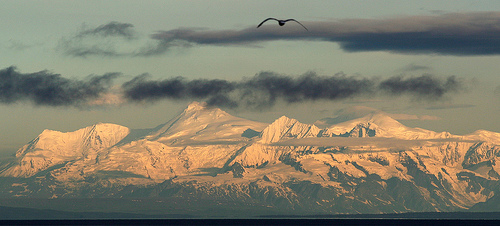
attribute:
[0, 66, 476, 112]
cloud — black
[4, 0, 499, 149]
sky — dark grey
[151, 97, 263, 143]
mountain — snow-covered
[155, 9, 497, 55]
cloud — grey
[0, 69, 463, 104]
cloud — grey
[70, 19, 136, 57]
cloud — grey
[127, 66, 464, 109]
grey cloud — dark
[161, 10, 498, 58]
grey cloud — dark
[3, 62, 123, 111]
grey cloud — dark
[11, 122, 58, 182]
mountains — rocky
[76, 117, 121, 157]
mountains — rocky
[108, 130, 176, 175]
mountains — rocky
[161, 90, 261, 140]
mountains — rocky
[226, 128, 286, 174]
mountains — rocky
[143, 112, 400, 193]
mountain — white, rocky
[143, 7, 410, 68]
cloud — black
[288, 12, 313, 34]
wing — bird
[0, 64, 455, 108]
cloud — black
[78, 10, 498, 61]
cloud — black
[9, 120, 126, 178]
moutain — snow-covered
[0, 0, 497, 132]
sky — white, grey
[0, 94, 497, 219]
mountains — snow-covered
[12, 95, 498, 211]
mountain — snow-covered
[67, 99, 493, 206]
mountains — white, tall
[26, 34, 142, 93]
cloud — dark, grey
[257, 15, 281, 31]
wing — extended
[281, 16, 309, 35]
wing — extended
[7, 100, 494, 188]
light — white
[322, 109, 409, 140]
mountain — snow-covered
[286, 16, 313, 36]
wing — opened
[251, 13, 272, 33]
wing — opened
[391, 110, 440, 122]
cloud — white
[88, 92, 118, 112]
cloud — white